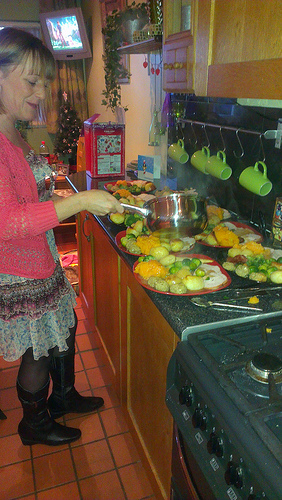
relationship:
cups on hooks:
[163, 137, 275, 196] [170, 115, 281, 162]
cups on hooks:
[163, 137, 275, 196] [171, 113, 280, 148]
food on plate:
[136, 247, 227, 294] [134, 253, 230, 295]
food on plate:
[220, 243, 281, 282] [112, 221, 197, 254]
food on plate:
[202, 222, 256, 247] [193, 220, 269, 248]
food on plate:
[115, 217, 197, 257] [102, 173, 155, 192]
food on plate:
[112, 189, 146, 205] [222, 239, 281, 284]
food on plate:
[132, 247, 231, 294] [115, 224, 197, 254]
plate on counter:
[115, 224, 197, 254] [176, 302, 193, 322]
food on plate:
[120, 214, 258, 299] [115, 224, 197, 254]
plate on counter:
[115, 224, 197, 254] [64, 146, 156, 190]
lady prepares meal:
[1, 25, 125, 447] [111, 171, 279, 299]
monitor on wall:
[38, 6, 91, 60] [39, 10, 129, 170]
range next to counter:
[211, 328, 281, 400] [164, 298, 207, 335]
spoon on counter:
[196, 292, 272, 318] [65, 162, 280, 498]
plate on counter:
[131, 276, 230, 308] [65, 138, 279, 315]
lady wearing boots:
[1, 25, 75, 325] [14, 350, 105, 446]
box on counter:
[74, 111, 137, 197] [89, 164, 242, 271]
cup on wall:
[238, 160, 272, 196] [166, 90, 281, 248]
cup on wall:
[206, 148, 232, 183] [166, 90, 281, 248]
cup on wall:
[190, 145, 208, 174] [166, 90, 281, 248]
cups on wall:
[167, 138, 191, 166] [166, 90, 281, 248]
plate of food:
[106, 179, 156, 197] [234, 245, 270, 279]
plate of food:
[115, 224, 197, 254] [234, 245, 270, 279]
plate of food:
[134, 253, 230, 295] [234, 245, 270, 279]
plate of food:
[195, 219, 262, 247] [234, 245, 270, 279]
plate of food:
[226, 242, 280, 280] [234, 245, 270, 279]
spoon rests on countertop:
[189, 292, 271, 319] [145, 243, 279, 339]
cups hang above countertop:
[163, 137, 275, 196] [64, 166, 280, 338]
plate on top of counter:
[134, 253, 230, 295] [71, 164, 281, 337]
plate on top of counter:
[195, 219, 262, 247] [71, 164, 281, 337]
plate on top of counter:
[115, 224, 197, 254] [71, 164, 281, 337]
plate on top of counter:
[106, 179, 156, 197] [71, 164, 281, 337]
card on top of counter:
[135, 152, 161, 183] [62, 165, 278, 329]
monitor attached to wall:
[38, 6, 91, 67] [1, 2, 156, 174]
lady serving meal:
[1, 25, 125, 447] [100, 197, 239, 320]